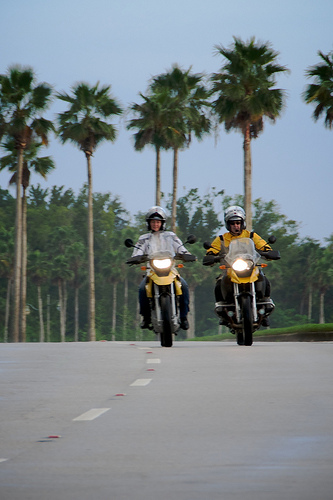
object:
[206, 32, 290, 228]
tree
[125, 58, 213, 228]
tree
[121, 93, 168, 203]
tree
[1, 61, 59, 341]
tree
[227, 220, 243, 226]
sunglasses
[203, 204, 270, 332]
man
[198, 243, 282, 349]
motorcycle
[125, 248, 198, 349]
motorcycle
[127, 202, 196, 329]
person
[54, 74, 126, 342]
tree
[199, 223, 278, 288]
coat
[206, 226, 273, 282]
coat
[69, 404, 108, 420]
line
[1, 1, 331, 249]
sky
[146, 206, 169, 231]
helmet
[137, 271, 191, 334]
pants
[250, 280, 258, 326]
support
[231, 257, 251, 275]
light